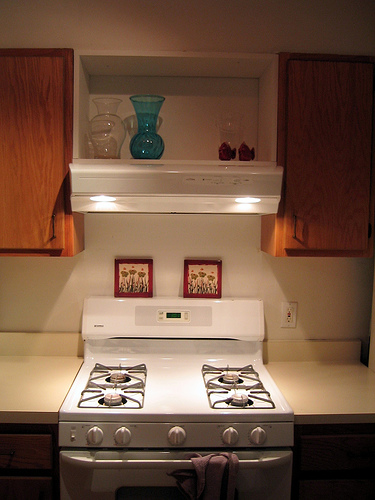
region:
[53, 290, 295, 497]
white stove and oven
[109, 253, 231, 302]
two paintings resting on a stove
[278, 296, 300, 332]
white outlet on the wall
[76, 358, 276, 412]
four burners on a stovetop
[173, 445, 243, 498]
towel hanging on an oven door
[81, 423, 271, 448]
five knobs on an oven range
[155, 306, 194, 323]
digital display on a stove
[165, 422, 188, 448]
oven knob in the center of a stove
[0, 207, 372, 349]
white wall in a kitchen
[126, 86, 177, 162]
blue vase above an oven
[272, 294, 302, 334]
Plug in on wall.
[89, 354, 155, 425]
Gas stove in kitchen.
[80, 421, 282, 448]
Five knobs on front of stove.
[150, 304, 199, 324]
Digital read out on oven top.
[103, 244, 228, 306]
Identical pictures on back of stove.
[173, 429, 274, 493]
Pinkish brown dish towel on handle.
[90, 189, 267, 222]
Lights above stove.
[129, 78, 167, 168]
Blue vase above stove on shelf.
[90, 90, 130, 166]
Clear vase above stove on shelf.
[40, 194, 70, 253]
Black handle on cabinet door.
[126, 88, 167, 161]
A clear blue vase.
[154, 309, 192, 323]
A display on a stove.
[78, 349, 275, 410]
A white stovetop.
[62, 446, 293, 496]
A white oven door.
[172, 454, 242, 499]
A dishcloth.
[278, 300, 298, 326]
A white electrical outlet.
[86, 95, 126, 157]
A large clear vase.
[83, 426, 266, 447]
White knobs on a stove.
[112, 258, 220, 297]
Pictures above the stove.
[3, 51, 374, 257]
Brown wooden cabinets above the countertops.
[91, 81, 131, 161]
The clear vase on the left.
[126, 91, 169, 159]
The blue vase on the shelf.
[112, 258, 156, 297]
The frame on the left.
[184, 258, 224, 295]
The frame on the right.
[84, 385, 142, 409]
The bottom left burner of the stove.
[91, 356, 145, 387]
The top left burner of the stove.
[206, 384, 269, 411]
The bottom right burner of the stove.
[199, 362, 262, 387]
The top right burner of the stove.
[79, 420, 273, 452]
The knobs on the stove.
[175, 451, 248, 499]
The towel hanging from the oven door.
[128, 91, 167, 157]
clear blue vase on a white shelf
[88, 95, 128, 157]
clear vase on a white shelf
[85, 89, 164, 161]
two clear vases on a shelf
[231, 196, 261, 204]
lit white light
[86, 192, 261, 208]
two lit white lights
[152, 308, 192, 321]
digital display on a white stove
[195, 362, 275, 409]
two stove burner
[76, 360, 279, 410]
four burners on a white stove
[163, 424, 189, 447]
white oven knob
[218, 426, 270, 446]
two white stove knobs